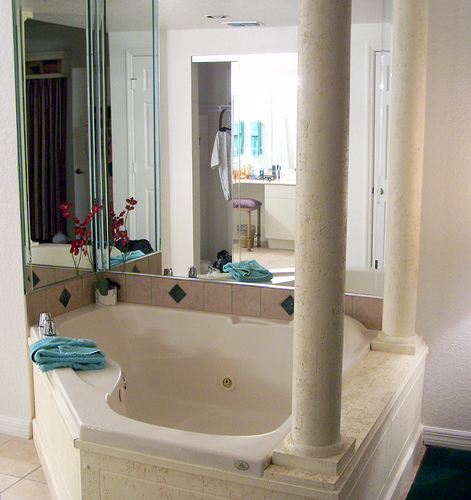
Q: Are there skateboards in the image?
A: No, there are no skateboards.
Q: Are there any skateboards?
A: No, there are no skateboards.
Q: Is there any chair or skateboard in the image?
A: No, there are no skateboards or chairs.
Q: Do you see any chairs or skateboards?
A: No, there are no skateboards or chairs.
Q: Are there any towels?
A: Yes, there is a towel.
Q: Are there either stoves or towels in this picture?
A: Yes, there is a towel.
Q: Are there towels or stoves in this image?
A: Yes, there is a towel.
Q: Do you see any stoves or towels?
A: Yes, there is a towel.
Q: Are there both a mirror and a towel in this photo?
A: Yes, there are both a towel and a mirror.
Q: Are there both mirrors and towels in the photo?
A: Yes, there are both a towel and a mirror.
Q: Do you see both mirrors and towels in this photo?
A: Yes, there are both a towel and a mirror.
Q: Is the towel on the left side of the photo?
A: Yes, the towel is on the left of the image.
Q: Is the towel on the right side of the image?
A: No, the towel is on the left of the image.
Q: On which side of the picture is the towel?
A: The towel is on the left of the image.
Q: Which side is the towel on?
A: The towel is on the left of the image.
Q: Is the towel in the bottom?
A: Yes, the towel is in the bottom of the image.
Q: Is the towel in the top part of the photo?
A: No, the towel is in the bottom of the image.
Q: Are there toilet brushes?
A: No, there are no toilet brushes.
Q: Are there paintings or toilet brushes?
A: No, there are no toilet brushes or paintings.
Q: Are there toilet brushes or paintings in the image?
A: No, there are no toilet brushes or paintings.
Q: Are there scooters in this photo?
A: No, there are no scooters.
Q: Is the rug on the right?
A: Yes, the rug is on the right of the image.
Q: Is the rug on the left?
A: No, the rug is on the right of the image.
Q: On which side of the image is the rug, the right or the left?
A: The rug is on the right of the image.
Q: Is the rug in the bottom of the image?
A: Yes, the rug is in the bottom of the image.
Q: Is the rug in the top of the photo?
A: No, the rug is in the bottom of the image.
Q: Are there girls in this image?
A: No, there are no girls.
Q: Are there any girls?
A: No, there are no girls.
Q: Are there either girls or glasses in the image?
A: No, there are no girls or glasses.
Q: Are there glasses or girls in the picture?
A: No, there are no girls or glasses.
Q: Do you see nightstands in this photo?
A: No, there are no nightstands.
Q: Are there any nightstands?
A: No, there are no nightstands.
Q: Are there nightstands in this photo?
A: No, there are no nightstands.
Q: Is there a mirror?
A: Yes, there is a mirror.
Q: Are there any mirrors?
A: Yes, there is a mirror.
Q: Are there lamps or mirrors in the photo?
A: Yes, there is a mirror.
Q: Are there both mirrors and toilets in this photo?
A: No, there is a mirror but no toilets.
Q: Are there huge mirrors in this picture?
A: Yes, there is a huge mirror.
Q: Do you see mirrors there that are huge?
A: Yes, there is a mirror that is huge.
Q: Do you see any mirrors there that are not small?
A: Yes, there is a huge mirror.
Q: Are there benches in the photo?
A: No, there are no benches.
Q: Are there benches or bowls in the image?
A: No, there are no benches or bowls.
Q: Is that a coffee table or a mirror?
A: That is a mirror.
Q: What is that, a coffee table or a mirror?
A: That is a mirror.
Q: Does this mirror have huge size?
A: Yes, the mirror is huge.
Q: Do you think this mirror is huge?
A: Yes, the mirror is huge.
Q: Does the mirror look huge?
A: Yes, the mirror is huge.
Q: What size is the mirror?
A: The mirror is huge.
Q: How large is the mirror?
A: The mirror is huge.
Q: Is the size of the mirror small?
A: No, the mirror is huge.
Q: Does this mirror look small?
A: No, the mirror is huge.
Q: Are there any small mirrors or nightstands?
A: No, there is a mirror but it is huge.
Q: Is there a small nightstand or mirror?
A: No, there is a mirror but it is huge.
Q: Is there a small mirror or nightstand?
A: No, there is a mirror but it is huge.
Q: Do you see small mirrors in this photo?
A: No, there is a mirror but it is huge.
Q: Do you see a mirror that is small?
A: No, there is a mirror but it is huge.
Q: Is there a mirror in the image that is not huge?
A: No, there is a mirror but it is huge.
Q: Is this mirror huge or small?
A: The mirror is huge.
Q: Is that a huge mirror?
A: Yes, that is a huge mirror.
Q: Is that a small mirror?
A: No, that is a huge mirror.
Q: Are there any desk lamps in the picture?
A: No, there are no desk lamps.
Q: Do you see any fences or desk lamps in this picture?
A: No, there are no desk lamps or fences.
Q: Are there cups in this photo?
A: Yes, there is a cup.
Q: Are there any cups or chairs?
A: Yes, there is a cup.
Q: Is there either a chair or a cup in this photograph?
A: Yes, there is a cup.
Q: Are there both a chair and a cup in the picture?
A: No, there is a cup but no chairs.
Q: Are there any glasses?
A: No, there are no glasses.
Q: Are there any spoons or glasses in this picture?
A: No, there are no glasses or spoons.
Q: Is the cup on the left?
A: Yes, the cup is on the left of the image.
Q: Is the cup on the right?
A: No, the cup is on the left of the image.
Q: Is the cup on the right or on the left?
A: The cup is on the left of the image.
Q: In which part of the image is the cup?
A: The cup is on the left of the image.